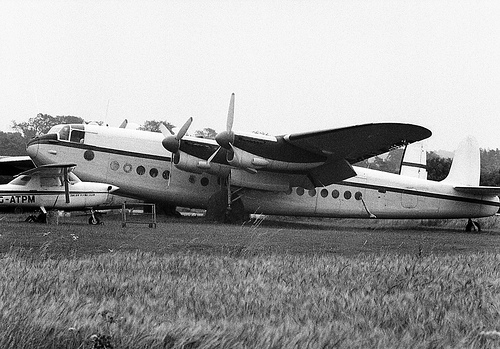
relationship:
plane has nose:
[24, 110, 499, 231] [24, 126, 58, 165]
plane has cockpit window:
[24, 110, 499, 231] [58, 120, 91, 151]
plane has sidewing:
[24, 110, 499, 231] [166, 112, 438, 194]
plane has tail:
[24, 110, 499, 231] [360, 158, 496, 230]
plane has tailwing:
[24, 110, 499, 231] [455, 178, 500, 203]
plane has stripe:
[24, 110, 499, 231] [46, 133, 498, 217]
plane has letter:
[5, 164, 122, 223] [7, 195, 16, 208]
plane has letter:
[5, 164, 122, 223] [15, 194, 22, 206]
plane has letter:
[5, 164, 122, 223] [20, 193, 28, 207]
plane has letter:
[5, 164, 122, 223] [26, 194, 37, 206]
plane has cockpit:
[24, 110, 499, 231] [43, 116, 91, 162]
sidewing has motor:
[166, 112, 438, 194] [213, 115, 309, 184]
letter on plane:
[7, 195, 16, 208] [5, 164, 122, 223]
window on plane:
[137, 160, 146, 179] [24, 110, 499, 231]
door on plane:
[392, 183, 425, 213] [24, 110, 499, 231]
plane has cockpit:
[5, 164, 122, 223] [37, 170, 84, 191]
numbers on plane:
[67, 189, 101, 199] [5, 164, 122, 223]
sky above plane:
[4, 0, 494, 149] [24, 110, 499, 231]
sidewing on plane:
[166, 112, 438, 194] [24, 110, 499, 231]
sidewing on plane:
[1, 185, 56, 204] [5, 164, 122, 223]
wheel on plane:
[83, 203, 107, 229] [5, 164, 122, 223]